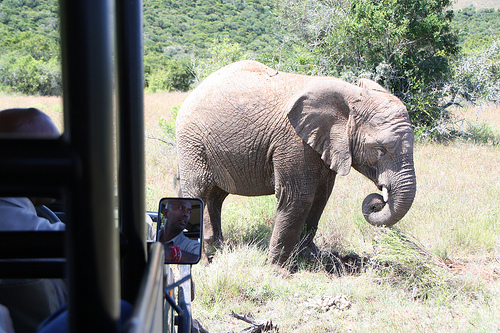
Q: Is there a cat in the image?
A: No, there are no cats.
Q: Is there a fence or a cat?
A: No, there are no cats or fences.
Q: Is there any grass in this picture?
A: Yes, there is grass.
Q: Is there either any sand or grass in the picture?
A: Yes, there is grass.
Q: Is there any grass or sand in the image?
A: Yes, there is grass.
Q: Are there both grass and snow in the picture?
A: No, there is grass but no snow.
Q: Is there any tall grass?
A: Yes, there is tall grass.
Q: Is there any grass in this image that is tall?
A: Yes, there is grass that is tall.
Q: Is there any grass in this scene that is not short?
A: Yes, there is tall grass.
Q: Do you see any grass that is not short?
A: Yes, there is tall grass.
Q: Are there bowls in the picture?
A: No, there are no bowls.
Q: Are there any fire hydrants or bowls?
A: No, there are no bowls or fire hydrants.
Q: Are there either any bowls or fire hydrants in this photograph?
A: No, there are no bowls or fire hydrants.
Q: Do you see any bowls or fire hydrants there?
A: No, there are no bowls or fire hydrants.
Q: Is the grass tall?
A: Yes, the grass is tall.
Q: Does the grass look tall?
A: Yes, the grass is tall.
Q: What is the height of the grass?
A: The grass is tall.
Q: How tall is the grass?
A: The grass is tall.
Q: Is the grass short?
A: No, the grass is tall.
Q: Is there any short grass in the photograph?
A: No, there is grass but it is tall.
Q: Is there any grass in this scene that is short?
A: No, there is grass but it is tall.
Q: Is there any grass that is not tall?
A: No, there is grass but it is tall.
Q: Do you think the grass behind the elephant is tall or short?
A: The grass is tall.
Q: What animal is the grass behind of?
A: The grass is behind the elephant.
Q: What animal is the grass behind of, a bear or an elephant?
A: The grass is behind an elephant.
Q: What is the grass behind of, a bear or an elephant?
A: The grass is behind an elephant.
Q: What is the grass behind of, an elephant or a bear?
A: The grass is behind an elephant.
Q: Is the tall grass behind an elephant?
A: Yes, the grass is behind an elephant.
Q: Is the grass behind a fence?
A: No, the grass is behind an elephant.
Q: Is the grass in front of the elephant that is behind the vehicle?
A: No, the grass is behind the elephant.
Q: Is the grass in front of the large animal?
A: No, the grass is behind the elephant.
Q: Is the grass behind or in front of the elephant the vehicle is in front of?
A: The grass is behind the elephant.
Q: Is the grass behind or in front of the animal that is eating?
A: The grass is behind the elephant.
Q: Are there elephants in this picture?
A: Yes, there is an elephant.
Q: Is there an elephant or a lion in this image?
A: Yes, there is an elephant.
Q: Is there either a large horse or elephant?
A: Yes, there is a large elephant.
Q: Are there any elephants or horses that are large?
A: Yes, the elephant is large.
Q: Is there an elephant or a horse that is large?
A: Yes, the elephant is large.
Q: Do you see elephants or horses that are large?
A: Yes, the elephant is large.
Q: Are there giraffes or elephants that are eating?
A: Yes, the elephant is eating.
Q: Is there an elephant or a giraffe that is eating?
A: Yes, the elephant is eating.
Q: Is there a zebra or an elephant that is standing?
A: Yes, the elephant is standing.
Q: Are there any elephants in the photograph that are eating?
A: Yes, there is an elephant that is eating.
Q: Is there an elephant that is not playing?
A: Yes, there is an elephant that is eating.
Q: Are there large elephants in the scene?
A: Yes, there is a large elephant.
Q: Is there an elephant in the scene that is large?
A: Yes, there is an elephant that is large.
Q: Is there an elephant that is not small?
A: Yes, there is a large elephant.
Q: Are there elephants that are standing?
A: Yes, there is an elephant that is standing.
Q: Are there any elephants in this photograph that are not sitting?
A: Yes, there is an elephant that is standing.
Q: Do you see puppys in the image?
A: No, there are no puppys.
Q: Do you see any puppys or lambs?
A: No, there are no puppys or lambs.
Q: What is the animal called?
A: The animal is an elephant.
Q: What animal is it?
A: The animal is an elephant.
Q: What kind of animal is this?
A: This is an elephant.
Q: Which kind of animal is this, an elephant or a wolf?
A: This is an elephant.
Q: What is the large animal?
A: The animal is an elephant.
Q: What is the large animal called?
A: The animal is an elephant.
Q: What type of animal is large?
A: The animal is an elephant.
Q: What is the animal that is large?
A: The animal is an elephant.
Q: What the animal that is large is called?
A: The animal is an elephant.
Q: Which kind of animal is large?
A: The animal is an elephant.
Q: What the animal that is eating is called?
A: The animal is an elephant.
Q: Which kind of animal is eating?
A: The animal is an elephant.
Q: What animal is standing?
A: The animal is an elephant.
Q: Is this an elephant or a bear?
A: This is an elephant.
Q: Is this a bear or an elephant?
A: This is an elephant.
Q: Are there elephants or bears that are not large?
A: No, there is an elephant but it is large.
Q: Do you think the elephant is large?
A: Yes, the elephant is large.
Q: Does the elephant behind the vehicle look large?
A: Yes, the elephant is large.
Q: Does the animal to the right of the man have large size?
A: Yes, the elephant is large.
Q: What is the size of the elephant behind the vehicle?
A: The elephant is large.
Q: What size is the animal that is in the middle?
A: The elephant is large.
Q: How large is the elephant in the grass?
A: The elephant is large.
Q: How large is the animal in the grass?
A: The elephant is large.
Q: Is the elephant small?
A: No, the elephant is large.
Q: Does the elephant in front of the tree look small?
A: No, the elephant is large.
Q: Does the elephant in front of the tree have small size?
A: No, the elephant is large.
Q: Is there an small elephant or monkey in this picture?
A: No, there is an elephant but it is large.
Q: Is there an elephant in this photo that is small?
A: No, there is an elephant but it is large.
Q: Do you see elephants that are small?
A: No, there is an elephant but it is large.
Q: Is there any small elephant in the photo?
A: No, there is an elephant but it is large.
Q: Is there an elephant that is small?
A: No, there is an elephant but it is large.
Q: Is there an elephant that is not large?
A: No, there is an elephant but it is large.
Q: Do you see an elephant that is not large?
A: No, there is an elephant but it is large.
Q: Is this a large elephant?
A: Yes, this is a large elephant.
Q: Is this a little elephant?
A: No, this is a large elephant.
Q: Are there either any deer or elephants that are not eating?
A: No, there is an elephant but it is eating.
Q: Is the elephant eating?
A: Yes, the elephant is eating.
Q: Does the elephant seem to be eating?
A: Yes, the elephant is eating.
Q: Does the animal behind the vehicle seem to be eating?
A: Yes, the elephant is eating.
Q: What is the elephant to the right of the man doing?
A: The elephant is eating.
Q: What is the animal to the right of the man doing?
A: The elephant is eating.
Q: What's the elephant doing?
A: The elephant is eating.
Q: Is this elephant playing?
A: No, the elephant is eating.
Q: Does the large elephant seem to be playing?
A: No, the elephant is eating.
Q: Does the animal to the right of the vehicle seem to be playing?
A: No, the elephant is eating.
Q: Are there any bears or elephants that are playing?
A: No, there is an elephant but it is eating.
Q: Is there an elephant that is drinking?
A: No, there is an elephant but it is eating.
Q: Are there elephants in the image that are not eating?
A: No, there is an elephant but it is eating.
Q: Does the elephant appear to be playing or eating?
A: The elephant is eating.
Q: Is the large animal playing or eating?
A: The elephant is eating.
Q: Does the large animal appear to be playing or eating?
A: The elephant is eating.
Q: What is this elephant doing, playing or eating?
A: The elephant is eating.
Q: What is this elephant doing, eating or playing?
A: The elephant is eating.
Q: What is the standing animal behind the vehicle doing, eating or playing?
A: The elephant is eating.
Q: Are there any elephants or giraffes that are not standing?
A: No, there is an elephant but it is standing.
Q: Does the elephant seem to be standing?
A: Yes, the elephant is standing.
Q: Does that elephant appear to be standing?
A: Yes, the elephant is standing.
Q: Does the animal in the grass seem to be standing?
A: Yes, the elephant is standing.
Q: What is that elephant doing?
A: The elephant is standing.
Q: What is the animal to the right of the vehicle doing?
A: The elephant is standing.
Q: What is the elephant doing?
A: The elephant is standing.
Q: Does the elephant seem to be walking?
A: No, the elephant is standing.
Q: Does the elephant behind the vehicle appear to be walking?
A: No, the elephant is standing.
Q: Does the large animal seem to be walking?
A: No, the elephant is standing.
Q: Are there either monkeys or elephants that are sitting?
A: No, there is an elephant but it is standing.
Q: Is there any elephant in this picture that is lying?
A: No, there is an elephant but it is standing.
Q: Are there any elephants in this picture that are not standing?
A: No, there is an elephant but it is standing.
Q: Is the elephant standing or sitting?
A: The elephant is standing.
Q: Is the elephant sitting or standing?
A: The elephant is standing.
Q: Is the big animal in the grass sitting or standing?
A: The elephant is standing.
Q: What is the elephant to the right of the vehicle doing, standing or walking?
A: The elephant is standing.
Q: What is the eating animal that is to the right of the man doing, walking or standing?
A: The elephant is standing.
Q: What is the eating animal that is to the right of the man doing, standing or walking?
A: The elephant is standing.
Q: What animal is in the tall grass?
A: The elephant is in the grass.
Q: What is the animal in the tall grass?
A: The animal is an elephant.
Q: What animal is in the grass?
A: The animal is an elephant.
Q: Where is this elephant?
A: The elephant is in the grass.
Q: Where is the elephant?
A: The elephant is in the grass.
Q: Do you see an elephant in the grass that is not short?
A: Yes, there is an elephant in the grass.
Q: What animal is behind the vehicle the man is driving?
A: The animal is an elephant.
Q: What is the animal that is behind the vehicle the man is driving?
A: The animal is an elephant.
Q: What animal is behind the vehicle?
A: The animal is an elephant.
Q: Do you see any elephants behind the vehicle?
A: Yes, there is an elephant behind the vehicle.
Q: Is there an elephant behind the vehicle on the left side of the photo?
A: Yes, there is an elephant behind the vehicle.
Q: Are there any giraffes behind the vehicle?
A: No, there is an elephant behind the vehicle.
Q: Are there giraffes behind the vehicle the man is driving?
A: No, there is an elephant behind the vehicle.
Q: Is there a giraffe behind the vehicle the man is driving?
A: No, there is an elephant behind the vehicle.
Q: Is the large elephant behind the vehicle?
A: Yes, the elephant is behind the vehicle.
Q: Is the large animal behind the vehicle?
A: Yes, the elephant is behind the vehicle.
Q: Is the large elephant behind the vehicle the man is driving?
A: Yes, the elephant is behind the vehicle.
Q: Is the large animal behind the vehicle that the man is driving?
A: Yes, the elephant is behind the vehicle.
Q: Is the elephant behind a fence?
A: No, the elephant is behind the vehicle.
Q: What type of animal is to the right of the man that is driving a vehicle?
A: The animal is an elephant.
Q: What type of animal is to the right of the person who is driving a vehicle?
A: The animal is an elephant.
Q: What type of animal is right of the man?
A: The animal is an elephant.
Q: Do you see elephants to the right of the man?
A: Yes, there is an elephant to the right of the man.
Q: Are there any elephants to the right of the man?
A: Yes, there is an elephant to the right of the man.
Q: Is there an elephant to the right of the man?
A: Yes, there is an elephant to the right of the man.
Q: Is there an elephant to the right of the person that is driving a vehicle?
A: Yes, there is an elephant to the right of the man.